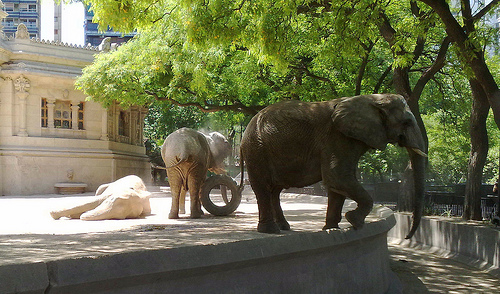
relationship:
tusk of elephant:
[414, 145, 434, 163] [223, 97, 445, 232]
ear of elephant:
[333, 91, 392, 150] [227, 72, 445, 239]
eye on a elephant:
[397, 111, 416, 131] [248, 99, 432, 233]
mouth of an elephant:
[392, 133, 406, 147] [236, 90, 428, 237]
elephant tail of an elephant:
[236, 145, 244, 195] [236, 90, 428, 237]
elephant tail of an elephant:
[149, 153, 189, 170] [159, 130, 234, 221]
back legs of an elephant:
[248, 185, 293, 233] [242, 80, 448, 241]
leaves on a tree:
[85, 2, 473, 164] [107, 17, 499, 144]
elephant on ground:
[44, 157, 172, 259] [13, 192, 499, 282]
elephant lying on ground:
[44, 157, 172, 259] [13, 192, 499, 282]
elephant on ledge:
[236, 90, 428, 237] [5, 211, 403, 294]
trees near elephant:
[73, 0, 498, 220] [48, 174, 150, 222]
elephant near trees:
[48, 174, 150, 222] [73, 0, 498, 220]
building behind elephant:
[2, 5, 174, 189] [236, 90, 428, 237]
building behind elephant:
[2, 5, 174, 189] [152, 115, 237, 216]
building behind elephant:
[2, 5, 174, 189] [47, 165, 163, 228]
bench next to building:
[52, 181, 88, 193] [0, 27, 158, 196]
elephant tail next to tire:
[236, 145, 244, 195] [198, 165, 251, 221]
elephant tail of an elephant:
[236, 145, 244, 195] [236, 93, 429, 239]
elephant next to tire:
[236, 93, 429, 239] [198, 165, 251, 221]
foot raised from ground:
[343, 201, 378, 231] [199, 216, 247, 236]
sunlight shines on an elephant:
[0, 173, 255, 241] [53, 170, 151, 230]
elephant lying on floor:
[48, 174, 154, 222] [2, 186, 499, 266]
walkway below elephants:
[380, 219, 490, 291] [44, 80, 433, 245]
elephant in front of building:
[149, 128, 232, 220] [0, 27, 158, 196]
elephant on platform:
[236, 93, 429, 239] [221, 216, 389, 291]